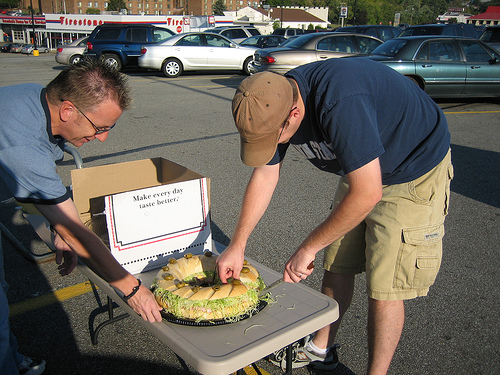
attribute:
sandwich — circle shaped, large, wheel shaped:
[149, 252, 267, 323]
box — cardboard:
[66, 157, 212, 276]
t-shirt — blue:
[257, 56, 451, 184]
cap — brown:
[227, 69, 296, 168]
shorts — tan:
[322, 147, 454, 300]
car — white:
[137, 31, 263, 76]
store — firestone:
[42, 14, 197, 53]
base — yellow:
[31, 50, 40, 57]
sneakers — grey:
[267, 336, 346, 371]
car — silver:
[246, 31, 384, 91]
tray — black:
[146, 278, 290, 327]